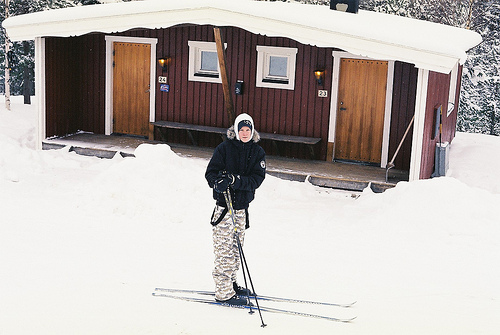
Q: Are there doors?
A: Yes, there are doors.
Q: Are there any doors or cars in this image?
A: Yes, there are doors.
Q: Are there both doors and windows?
A: Yes, there are both doors and a window.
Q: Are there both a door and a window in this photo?
A: Yes, there are both a door and a window.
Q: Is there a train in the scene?
A: No, there are no trains.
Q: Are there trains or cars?
A: No, there are no trains or cars.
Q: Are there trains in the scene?
A: No, there are no trains.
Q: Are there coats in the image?
A: Yes, there is a coat.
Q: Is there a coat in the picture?
A: Yes, there is a coat.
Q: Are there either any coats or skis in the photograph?
A: Yes, there is a coat.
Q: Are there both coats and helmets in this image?
A: No, there is a coat but no helmets.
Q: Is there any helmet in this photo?
A: No, there are no helmets.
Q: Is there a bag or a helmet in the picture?
A: No, there are no helmets or bags.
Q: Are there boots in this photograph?
A: Yes, there are boots.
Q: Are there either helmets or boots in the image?
A: Yes, there are boots.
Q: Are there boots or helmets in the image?
A: Yes, there are boots.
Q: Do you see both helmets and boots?
A: No, there are boots but no helmets.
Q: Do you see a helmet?
A: No, there are no helmets.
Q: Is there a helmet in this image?
A: No, there are no helmets.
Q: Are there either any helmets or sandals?
A: No, there are no helmets or sandals.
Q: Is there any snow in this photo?
A: Yes, there is snow.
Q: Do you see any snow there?
A: Yes, there is snow.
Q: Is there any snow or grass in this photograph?
A: Yes, there is snow.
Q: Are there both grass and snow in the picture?
A: No, there is snow but no grass.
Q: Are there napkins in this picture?
A: No, there are no napkins.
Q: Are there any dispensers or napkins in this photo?
A: No, there are no napkins or dispensers.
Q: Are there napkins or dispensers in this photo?
A: No, there are no napkins or dispensers.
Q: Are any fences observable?
A: No, there are no fences.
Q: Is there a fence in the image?
A: No, there are no fences.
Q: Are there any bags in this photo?
A: No, there are no bags.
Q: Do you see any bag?
A: No, there are no bags.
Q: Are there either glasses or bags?
A: No, there are no bags or glasses.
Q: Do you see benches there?
A: Yes, there is a bench.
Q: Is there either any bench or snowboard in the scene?
A: Yes, there is a bench.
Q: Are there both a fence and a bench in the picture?
A: No, there is a bench but no fences.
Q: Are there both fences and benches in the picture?
A: No, there is a bench but no fences.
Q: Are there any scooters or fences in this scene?
A: No, there are no fences or scooters.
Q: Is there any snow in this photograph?
A: Yes, there is snow.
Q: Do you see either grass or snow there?
A: Yes, there is snow.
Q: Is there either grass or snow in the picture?
A: Yes, there is snow.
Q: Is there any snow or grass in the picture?
A: Yes, there is snow.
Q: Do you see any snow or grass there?
A: Yes, there is snow.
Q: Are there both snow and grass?
A: No, there is snow but no grass.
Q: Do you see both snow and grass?
A: No, there is snow but no grass.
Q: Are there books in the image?
A: No, there are no books.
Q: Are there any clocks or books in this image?
A: No, there are no books or clocks.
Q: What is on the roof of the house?
A: The snow is on the roof.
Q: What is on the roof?
A: The snow is on the roof.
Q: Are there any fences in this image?
A: No, there are no fences.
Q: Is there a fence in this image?
A: No, there are no fences.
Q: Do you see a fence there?
A: No, there are no fences.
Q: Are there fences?
A: No, there are no fences.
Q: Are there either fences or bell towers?
A: No, there are no fences or bell towers.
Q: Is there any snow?
A: Yes, there is snow.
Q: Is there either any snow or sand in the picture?
A: Yes, there is snow.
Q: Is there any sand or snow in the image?
A: Yes, there is snow.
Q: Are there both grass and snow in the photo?
A: No, there is snow but no grass.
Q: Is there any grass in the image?
A: No, there is no grass.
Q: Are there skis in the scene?
A: Yes, there are skis.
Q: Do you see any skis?
A: Yes, there are skis.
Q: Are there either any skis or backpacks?
A: Yes, there are skis.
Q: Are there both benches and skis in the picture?
A: Yes, there are both skis and a bench.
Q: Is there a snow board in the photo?
A: No, there are no snowboards.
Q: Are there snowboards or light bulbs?
A: No, there are no snowboards or light bulbs.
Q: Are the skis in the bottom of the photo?
A: Yes, the skis are in the bottom of the image.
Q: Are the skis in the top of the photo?
A: No, the skis are in the bottom of the image.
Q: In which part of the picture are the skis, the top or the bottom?
A: The skis are in the bottom of the image.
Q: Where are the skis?
A: The skis are in the snow.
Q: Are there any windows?
A: Yes, there is a window.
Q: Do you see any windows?
A: Yes, there is a window.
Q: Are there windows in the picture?
A: Yes, there is a window.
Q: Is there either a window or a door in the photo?
A: Yes, there is a window.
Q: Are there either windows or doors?
A: Yes, there is a window.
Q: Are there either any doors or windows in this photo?
A: Yes, there is a window.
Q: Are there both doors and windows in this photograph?
A: Yes, there are both a window and a door.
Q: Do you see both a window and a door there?
A: Yes, there are both a window and a door.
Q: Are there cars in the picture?
A: No, there are no cars.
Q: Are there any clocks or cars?
A: No, there are no cars or clocks.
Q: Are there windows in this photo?
A: Yes, there is a window.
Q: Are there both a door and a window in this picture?
A: Yes, there are both a window and a door.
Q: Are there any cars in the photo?
A: No, there are no cars.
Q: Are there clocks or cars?
A: No, there are no cars or clocks.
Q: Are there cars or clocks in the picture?
A: No, there are no cars or clocks.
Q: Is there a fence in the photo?
A: No, there are no fences.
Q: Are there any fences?
A: No, there are no fences.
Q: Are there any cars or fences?
A: No, there are no fences or cars.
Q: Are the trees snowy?
A: Yes, the trees are snowy.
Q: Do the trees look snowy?
A: Yes, the trees are snowy.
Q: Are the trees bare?
A: No, the trees are snowy.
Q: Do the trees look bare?
A: No, the trees are snowy.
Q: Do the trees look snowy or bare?
A: The trees are snowy.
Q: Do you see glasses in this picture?
A: No, there are no glasses.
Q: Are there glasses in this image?
A: No, there are no glasses.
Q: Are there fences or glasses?
A: No, there are no glasses or fences.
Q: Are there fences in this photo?
A: No, there are no fences.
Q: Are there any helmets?
A: No, there are no helmets.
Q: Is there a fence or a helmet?
A: No, there are no helmets or fences.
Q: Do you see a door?
A: Yes, there is a door.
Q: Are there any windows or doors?
A: Yes, there is a door.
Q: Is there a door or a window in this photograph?
A: Yes, there is a door.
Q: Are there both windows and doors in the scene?
A: Yes, there are both a door and a window.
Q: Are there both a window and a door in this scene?
A: Yes, there are both a door and a window.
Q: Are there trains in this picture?
A: No, there are no trains.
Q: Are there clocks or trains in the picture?
A: No, there are no trains or clocks.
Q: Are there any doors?
A: Yes, there is a door.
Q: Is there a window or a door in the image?
A: Yes, there is a door.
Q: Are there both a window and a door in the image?
A: Yes, there are both a door and a window.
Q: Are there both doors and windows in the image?
A: Yes, there are both a door and a window.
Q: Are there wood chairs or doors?
A: Yes, there is a wood door.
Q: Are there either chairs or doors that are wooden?
A: Yes, the door is wooden.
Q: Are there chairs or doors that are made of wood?
A: Yes, the door is made of wood.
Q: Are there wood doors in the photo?
A: Yes, there is a wood door.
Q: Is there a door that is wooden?
A: Yes, there is a door that is wooden.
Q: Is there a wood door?
A: Yes, there is a door that is made of wood.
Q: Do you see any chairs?
A: No, there are no chairs.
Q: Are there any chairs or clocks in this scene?
A: No, there are no chairs or clocks.